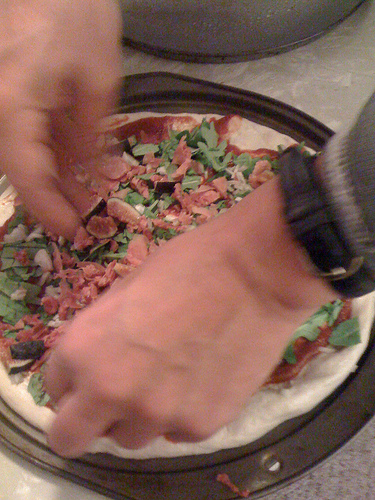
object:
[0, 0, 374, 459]
person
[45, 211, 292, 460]
hand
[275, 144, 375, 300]
watch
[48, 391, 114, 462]
finger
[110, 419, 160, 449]
finger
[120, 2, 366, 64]
plate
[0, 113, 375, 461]
pizza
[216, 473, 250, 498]
topping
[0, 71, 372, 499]
pan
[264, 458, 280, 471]
hole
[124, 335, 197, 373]
vein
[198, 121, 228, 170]
leaf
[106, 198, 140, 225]
topping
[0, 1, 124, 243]
hand